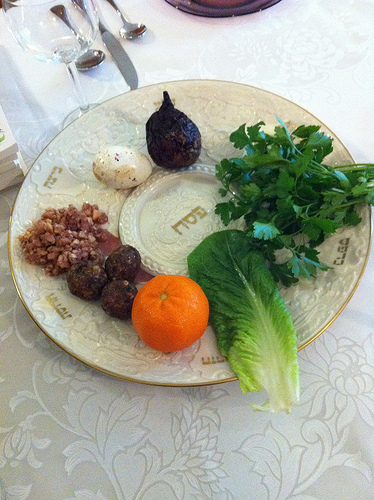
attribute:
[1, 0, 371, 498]
tablecloth — floral design, floral, embossed, linen, white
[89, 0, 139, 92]
knife — silver, metal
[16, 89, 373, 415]
food — healthy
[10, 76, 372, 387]
plate — round, white, decorative, designed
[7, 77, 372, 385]
border — gold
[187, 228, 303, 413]
romaine lettuce — piece, large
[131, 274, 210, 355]
orange — small, bright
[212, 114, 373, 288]
parsley — green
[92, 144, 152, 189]
egg — exotic, boiled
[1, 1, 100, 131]
wine glass — clear, transparent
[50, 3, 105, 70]
spoon — metal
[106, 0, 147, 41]
spoon — metal